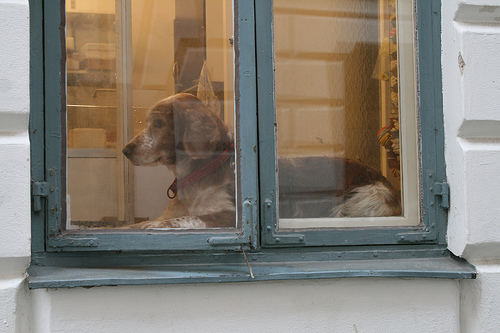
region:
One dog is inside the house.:
[109, 67, 397, 247]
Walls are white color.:
[306, 290, 392, 328]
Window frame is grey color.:
[231, 206, 436, 287]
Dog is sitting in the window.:
[130, 90, 411, 238]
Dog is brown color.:
[145, 98, 382, 225]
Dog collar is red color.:
[162, 153, 252, 189]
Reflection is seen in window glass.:
[96, 28, 408, 209]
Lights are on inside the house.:
[72, 12, 377, 153]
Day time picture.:
[7, 50, 485, 327]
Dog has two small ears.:
[172, 101, 232, 173]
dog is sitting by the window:
[86, 56, 441, 256]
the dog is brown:
[111, 69, 432, 264]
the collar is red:
[154, 138, 277, 218]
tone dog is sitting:
[130, 75, 496, 310]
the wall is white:
[248, 292, 409, 330]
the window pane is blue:
[31, 13, 466, 291]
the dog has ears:
[146, 81, 243, 178]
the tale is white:
[331, 187, 423, 240]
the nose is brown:
[101, 82, 167, 180]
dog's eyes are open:
[139, 107, 193, 166]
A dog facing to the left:
[120, 109, 395, 219]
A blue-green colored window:
[235, 4, 447, 254]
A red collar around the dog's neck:
[162, 140, 232, 200]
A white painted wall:
[444, 4, 498, 244]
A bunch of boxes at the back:
[63, 33, 114, 73]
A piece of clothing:
[189, 60, 224, 117]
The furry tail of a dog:
[335, 166, 402, 221]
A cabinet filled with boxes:
[66, 1, 125, 221]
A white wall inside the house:
[286, 5, 367, 150]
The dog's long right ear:
[166, 99, 221, 162]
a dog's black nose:
[116, 134, 148, 169]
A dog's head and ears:
[124, 88, 230, 178]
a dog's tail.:
[327, 172, 400, 217]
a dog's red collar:
[162, 147, 234, 201]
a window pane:
[65, 0, 234, 225]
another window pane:
[273, 0, 396, 212]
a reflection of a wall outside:
[274, 2, 342, 154]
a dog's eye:
[151, 112, 168, 136]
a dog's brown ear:
[179, 109, 229, 164]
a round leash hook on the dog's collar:
[161, 181, 178, 203]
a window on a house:
[263, 0, 416, 234]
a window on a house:
[61, 0, 243, 238]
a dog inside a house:
[119, 85, 396, 229]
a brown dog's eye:
[153, 116, 168, 133]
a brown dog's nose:
[121, 142, 136, 156]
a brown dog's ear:
[183, 107, 217, 152]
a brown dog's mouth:
[128, 150, 166, 175]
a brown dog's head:
[116, 81, 216, 173]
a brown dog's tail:
[331, 170, 398, 218]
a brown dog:
[113, 77, 410, 229]